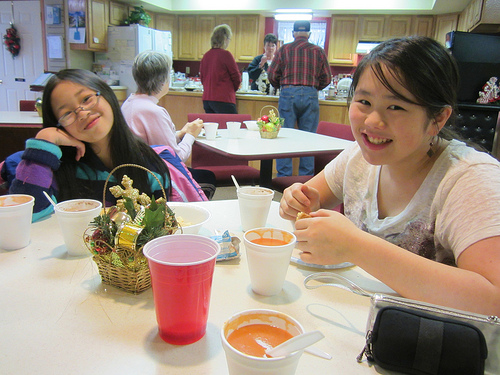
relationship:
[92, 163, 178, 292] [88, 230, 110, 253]
basket has flowers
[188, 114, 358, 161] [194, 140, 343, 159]
counter has edge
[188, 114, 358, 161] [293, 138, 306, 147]
counter has part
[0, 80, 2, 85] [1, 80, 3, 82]
handle has part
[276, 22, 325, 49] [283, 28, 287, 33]
shade has part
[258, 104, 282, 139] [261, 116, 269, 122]
basket has fruit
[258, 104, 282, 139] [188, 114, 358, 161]
basket on top of counter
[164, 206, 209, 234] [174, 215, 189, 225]
bowl has ice cream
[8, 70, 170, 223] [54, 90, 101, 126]
person has glasses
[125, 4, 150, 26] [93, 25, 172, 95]
plant on top of refrigerator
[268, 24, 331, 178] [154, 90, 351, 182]
person next to counter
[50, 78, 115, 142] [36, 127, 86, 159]
head on top of hand